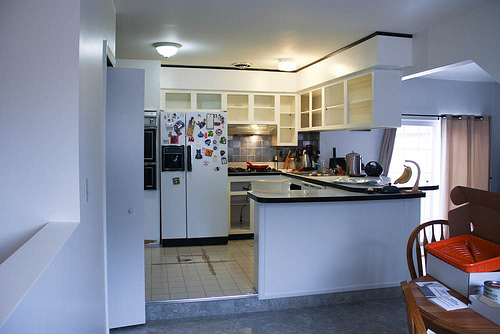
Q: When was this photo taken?
A: Daytime.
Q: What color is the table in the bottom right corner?
A: Brown.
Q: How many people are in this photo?
A: Zero.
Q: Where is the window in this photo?
A: Far right.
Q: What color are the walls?
A: White.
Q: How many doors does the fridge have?
A: Two.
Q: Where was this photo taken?
A: In the kitchen.